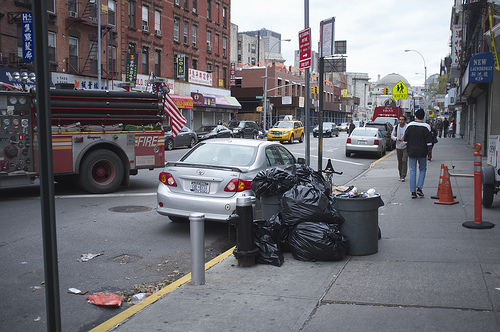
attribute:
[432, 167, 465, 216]
cones — orange, construction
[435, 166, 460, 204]
cone — orange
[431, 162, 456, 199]
cone — orange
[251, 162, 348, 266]
bags — big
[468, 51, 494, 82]
sign — blue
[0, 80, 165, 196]
firetruck — veering, red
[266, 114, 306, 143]
taxi — suv, yellow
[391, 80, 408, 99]
pedestrian sign — posted, black, yellow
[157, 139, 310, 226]
sedan — gray, small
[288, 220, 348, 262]
bag — black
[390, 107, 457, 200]
people — walking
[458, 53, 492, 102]
awning — blue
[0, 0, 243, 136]
building — red brick, huge, large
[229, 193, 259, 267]
fire hydrant — black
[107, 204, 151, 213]
mahole cover — present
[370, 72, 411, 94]
building — domed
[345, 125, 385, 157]
vehicle — parked, silver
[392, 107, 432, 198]
pedestrians — strolling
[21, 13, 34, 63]
sign — blue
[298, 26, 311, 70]
sign — red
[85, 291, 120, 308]
rubbish — red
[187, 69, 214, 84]
sign — white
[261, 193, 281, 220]
trash can — gray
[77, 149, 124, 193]
tire — black, large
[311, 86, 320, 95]
traffic signal — yellow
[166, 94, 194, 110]
awning — red